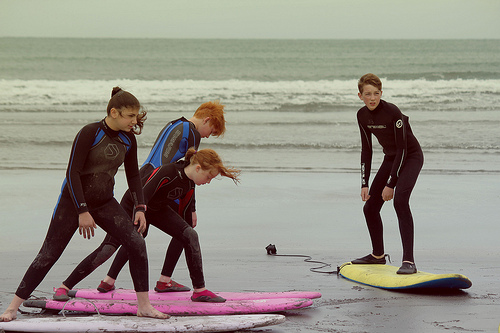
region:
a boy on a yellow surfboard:
[337, 72, 472, 292]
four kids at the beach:
[3, 73, 474, 331]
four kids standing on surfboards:
[2, 72, 474, 332]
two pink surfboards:
[24, 289, 324, 313]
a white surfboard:
[0, 314, 287, 331]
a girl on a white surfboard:
[0, 87, 283, 332]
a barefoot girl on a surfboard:
[0, 84, 172, 321]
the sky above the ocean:
[2, 0, 499, 37]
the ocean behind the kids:
[0, 38, 498, 170]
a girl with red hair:
[46, 147, 240, 301]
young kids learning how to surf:
[38, 58, 468, 331]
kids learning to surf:
[1, 5, 471, 329]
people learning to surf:
[5, 1, 473, 330]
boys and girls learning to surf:
[16, 12, 493, 329]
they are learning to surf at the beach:
[8, 11, 495, 331]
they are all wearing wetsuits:
[4, 1, 499, 320]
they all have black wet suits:
[3, 2, 445, 331]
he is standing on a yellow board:
[328, 60, 495, 307]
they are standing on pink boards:
[158, 90, 349, 309]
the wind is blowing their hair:
[3, 36, 493, 331]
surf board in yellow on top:
[337, 256, 467, 293]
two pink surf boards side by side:
[38, 287, 322, 313]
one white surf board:
[6, 314, 289, 331]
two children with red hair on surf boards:
[145, 99, 240, 304]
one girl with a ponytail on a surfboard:
[62, 86, 154, 317]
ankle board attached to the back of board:
[264, 244, 344, 273]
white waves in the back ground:
[190, 82, 345, 107]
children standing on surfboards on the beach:
[22, 77, 487, 330]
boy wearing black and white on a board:
[347, 68, 424, 275]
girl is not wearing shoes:
[1, 302, 174, 323]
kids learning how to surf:
[1, 69, 499, 331]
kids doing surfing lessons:
[3, 63, 498, 325]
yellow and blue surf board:
[333, 257, 480, 294]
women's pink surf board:
[30, 293, 320, 313]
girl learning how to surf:
[8, 75, 167, 326]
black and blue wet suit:
[56, 117, 153, 294]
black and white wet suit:
[353, 94, 424, 260]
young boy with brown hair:
[353, 70, 387, 110]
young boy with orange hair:
[192, 96, 228, 140]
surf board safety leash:
[266, 241, 341, 279]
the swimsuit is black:
[347, 111, 430, 281]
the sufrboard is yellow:
[349, 253, 466, 297]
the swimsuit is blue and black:
[67, 126, 157, 287]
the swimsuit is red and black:
[149, 155, 210, 285]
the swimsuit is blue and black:
[154, 107, 199, 167]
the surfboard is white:
[42, 312, 271, 332]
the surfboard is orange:
[47, 292, 283, 307]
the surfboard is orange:
[78, 283, 325, 298]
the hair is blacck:
[90, 87, 147, 113]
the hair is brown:
[187, 139, 229, 186]